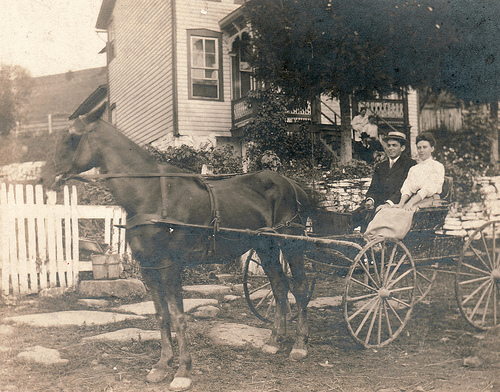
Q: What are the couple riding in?
A: A horse drawn buggy.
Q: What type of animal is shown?
A: Horse.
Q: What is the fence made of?
A: Wood.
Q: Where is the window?
A: On the building.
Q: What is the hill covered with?
A: Grass.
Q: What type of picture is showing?
A: Black and white.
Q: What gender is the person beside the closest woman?
A: Male.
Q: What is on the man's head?
A: Hat.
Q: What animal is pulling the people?
A: Horse.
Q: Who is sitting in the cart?
A: Man and woman.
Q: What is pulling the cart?
A: Horse.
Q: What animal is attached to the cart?
A: Horse.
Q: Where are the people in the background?
A: Steps.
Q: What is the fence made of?
A: Wood.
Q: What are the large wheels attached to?
A: Cart.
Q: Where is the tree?
A: Near the staircase.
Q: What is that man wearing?
A: A suit.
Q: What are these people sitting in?
A: A carriage.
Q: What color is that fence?
A: White.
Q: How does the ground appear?
A: Rocky.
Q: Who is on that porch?
A: People.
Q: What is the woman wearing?
A: A dress.